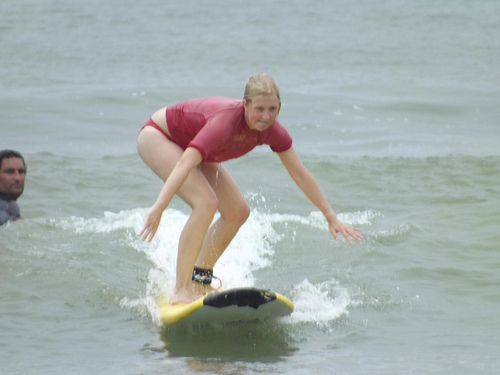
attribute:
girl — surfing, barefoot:
[131, 73, 361, 288]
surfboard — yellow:
[149, 281, 294, 329]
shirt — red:
[164, 94, 295, 159]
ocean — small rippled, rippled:
[1, 1, 496, 374]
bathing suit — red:
[135, 117, 178, 147]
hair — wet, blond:
[244, 72, 279, 106]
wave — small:
[9, 211, 458, 329]